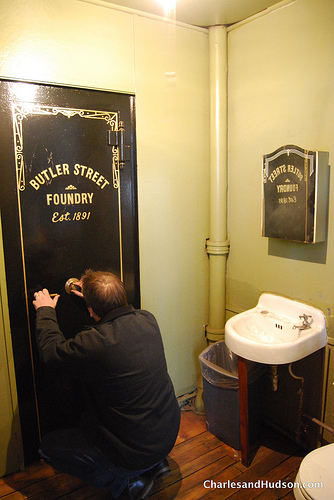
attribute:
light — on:
[159, 3, 185, 24]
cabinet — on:
[258, 143, 323, 253]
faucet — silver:
[291, 310, 323, 332]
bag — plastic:
[190, 331, 279, 389]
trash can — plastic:
[191, 327, 267, 462]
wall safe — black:
[0, 74, 165, 483]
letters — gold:
[20, 156, 117, 233]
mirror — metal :
[259, 140, 315, 240]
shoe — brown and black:
[147, 455, 173, 477]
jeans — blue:
[39, 439, 178, 491]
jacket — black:
[23, 289, 193, 480]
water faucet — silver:
[286, 307, 319, 336]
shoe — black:
[148, 456, 174, 484]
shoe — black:
[122, 466, 154, 496]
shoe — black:
[110, 466, 159, 497]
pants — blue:
[34, 420, 178, 496]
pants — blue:
[21, 423, 180, 491]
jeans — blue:
[24, 415, 203, 490]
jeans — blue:
[32, 445, 191, 496]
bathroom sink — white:
[215, 275, 329, 400]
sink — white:
[212, 275, 331, 375]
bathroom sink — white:
[210, 288, 332, 383]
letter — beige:
[23, 179, 41, 191]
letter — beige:
[34, 172, 47, 186]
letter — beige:
[40, 166, 49, 182]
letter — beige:
[46, 165, 58, 178]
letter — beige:
[52, 162, 62, 177]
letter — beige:
[62, 161, 71, 174]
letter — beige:
[43, 192, 53, 210]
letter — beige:
[65, 190, 74, 207]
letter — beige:
[85, 189, 95, 204]